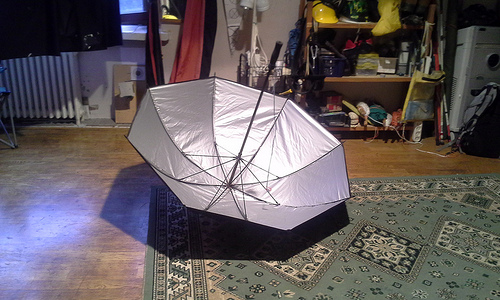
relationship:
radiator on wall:
[4, 44, 84, 125] [45, 9, 150, 169]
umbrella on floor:
[125, 37, 354, 237] [6, 103, 482, 292]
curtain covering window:
[6, 4, 131, 55] [118, 0, 154, 49]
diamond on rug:
[346, 222, 430, 281] [143, 175, 484, 287]